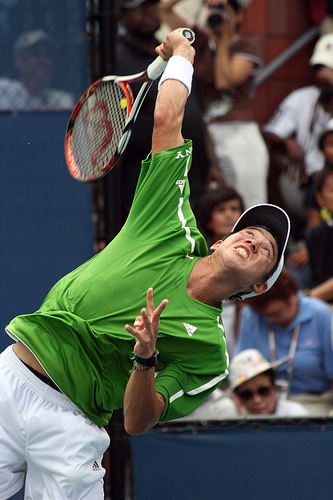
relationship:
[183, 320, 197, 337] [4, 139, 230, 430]
logo on shirt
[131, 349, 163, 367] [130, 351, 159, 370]
watch on wrist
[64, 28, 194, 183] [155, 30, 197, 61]
raquet in hand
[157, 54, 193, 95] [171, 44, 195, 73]
armband on wrist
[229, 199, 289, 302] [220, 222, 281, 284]
hat on head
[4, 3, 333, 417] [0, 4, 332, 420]
spectators in stands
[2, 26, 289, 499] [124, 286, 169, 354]
player has hand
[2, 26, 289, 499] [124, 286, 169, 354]
player flexing hand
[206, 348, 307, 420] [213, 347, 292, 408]
woman wearing hat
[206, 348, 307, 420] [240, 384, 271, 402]
woman wearing sunglasses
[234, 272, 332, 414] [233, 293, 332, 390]
person in blue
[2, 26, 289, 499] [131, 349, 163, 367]
player wearing watch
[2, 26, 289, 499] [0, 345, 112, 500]
player wearing shorts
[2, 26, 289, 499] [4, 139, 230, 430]
player wearing shirt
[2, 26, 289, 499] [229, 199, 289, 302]
player wearing hat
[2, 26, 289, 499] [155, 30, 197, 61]
player extending hand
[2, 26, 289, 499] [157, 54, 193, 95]
player wearing armband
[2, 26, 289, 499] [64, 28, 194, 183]
player holding raquet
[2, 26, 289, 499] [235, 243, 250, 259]
player gritting teeth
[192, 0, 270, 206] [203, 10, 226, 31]
woman using camera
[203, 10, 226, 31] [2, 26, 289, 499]
camera on player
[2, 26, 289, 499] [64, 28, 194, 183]
player swings raquet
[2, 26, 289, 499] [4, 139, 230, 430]
player in shirt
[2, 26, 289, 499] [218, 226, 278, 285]
player has face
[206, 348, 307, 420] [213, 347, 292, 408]
woman in hat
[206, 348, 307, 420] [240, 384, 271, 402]
woman in sunglasses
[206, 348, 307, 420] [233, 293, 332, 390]
woman in blue